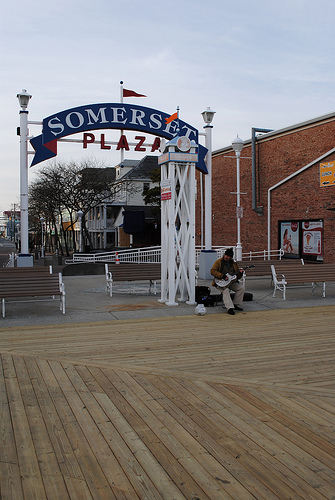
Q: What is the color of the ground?
A: Brown.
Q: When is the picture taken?
A: Daytime.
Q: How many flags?
A: 2.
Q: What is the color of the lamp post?
A: White.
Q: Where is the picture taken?
A: At Somerset Plaza.